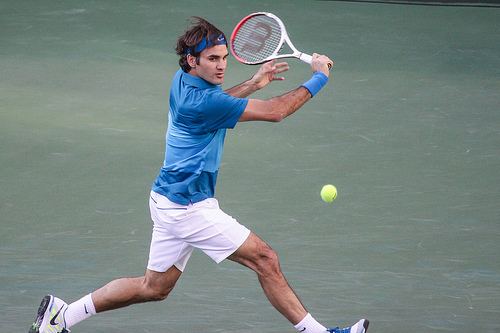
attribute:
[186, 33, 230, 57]
head band — blue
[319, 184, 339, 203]
tennis ball — yellow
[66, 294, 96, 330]
sock — white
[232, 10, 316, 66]
tennis racket — white, red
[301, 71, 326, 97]
wrist band — blue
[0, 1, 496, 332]
court — green, dark green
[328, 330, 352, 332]
shoelaces — blue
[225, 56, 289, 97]
arm — furry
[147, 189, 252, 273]
shorts — white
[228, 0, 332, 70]
tennis racket — white, red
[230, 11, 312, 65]
tennis racket — red and white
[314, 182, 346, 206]
ball — green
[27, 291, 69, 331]
shoe — white, blue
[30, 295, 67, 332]
shoe — Nike brand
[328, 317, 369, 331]
shoe — Nike brand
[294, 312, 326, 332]
sock — Nike brand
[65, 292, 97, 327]
sock — Nike brand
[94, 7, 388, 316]
tennis player — male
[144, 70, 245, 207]
shirt — stiped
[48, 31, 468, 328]
tennis court — green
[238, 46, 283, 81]
hands — light skinned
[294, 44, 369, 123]
hands — light skinned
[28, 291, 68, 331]
tennis shoe — striped, dark green, glow in the dark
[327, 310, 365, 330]
tennis shoe — striped, dark green, glow in the dark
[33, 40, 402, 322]
man — playing tennis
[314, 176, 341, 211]
tennis ball — yellow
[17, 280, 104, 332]
shoes — white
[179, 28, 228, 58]
sweatband — blue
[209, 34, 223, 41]
logo — Nike, white, little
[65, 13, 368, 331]
tennis player — good looking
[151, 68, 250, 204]
shirt — blue, wrinkly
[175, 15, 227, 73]
hair — dark brown, brown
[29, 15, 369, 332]
man — playing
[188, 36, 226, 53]
band — blue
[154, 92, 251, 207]
shirt — blue